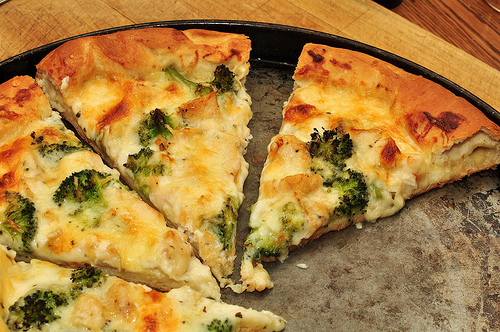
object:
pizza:
[1, 28, 500, 332]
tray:
[0, 18, 500, 332]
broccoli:
[322, 167, 370, 216]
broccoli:
[3, 287, 66, 332]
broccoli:
[52, 169, 115, 205]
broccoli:
[132, 109, 177, 148]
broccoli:
[306, 127, 354, 166]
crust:
[59, 28, 233, 66]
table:
[0, 0, 499, 332]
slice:
[0, 27, 254, 300]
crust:
[409, 96, 469, 136]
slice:
[240, 44, 499, 295]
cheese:
[173, 135, 251, 188]